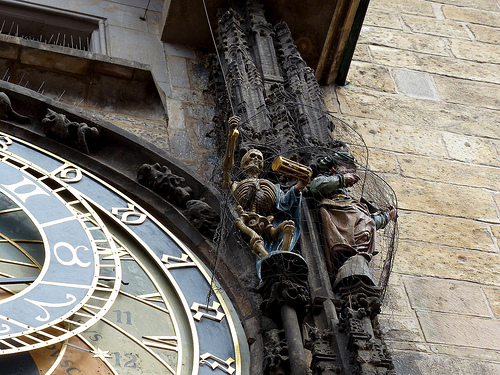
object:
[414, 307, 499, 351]
brick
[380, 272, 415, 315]
brick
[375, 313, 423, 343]
brick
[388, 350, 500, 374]
brick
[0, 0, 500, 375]
wall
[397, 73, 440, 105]
side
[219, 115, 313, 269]
skeleton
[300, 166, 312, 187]
hand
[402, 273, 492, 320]
brick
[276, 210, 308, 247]
knee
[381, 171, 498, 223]
brick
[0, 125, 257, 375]
clock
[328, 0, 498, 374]
stone wall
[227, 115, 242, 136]
hand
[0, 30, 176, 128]
ledge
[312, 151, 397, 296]
man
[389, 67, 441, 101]
brick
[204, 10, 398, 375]
pillar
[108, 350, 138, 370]
12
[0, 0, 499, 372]
building